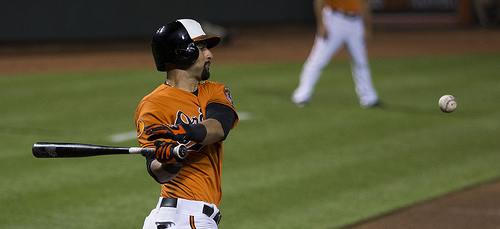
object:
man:
[135, 19, 236, 228]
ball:
[437, 93, 461, 115]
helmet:
[151, 19, 222, 70]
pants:
[143, 194, 222, 227]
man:
[295, 3, 389, 110]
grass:
[6, 56, 493, 227]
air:
[294, 39, 500, 206]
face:
[189, 41, 215, 84]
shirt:
[138, 81, 237, 205]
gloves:
[143, 122, 189, 142]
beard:
[200, 60, 210, 80]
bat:
[33, 139, 189, 161]